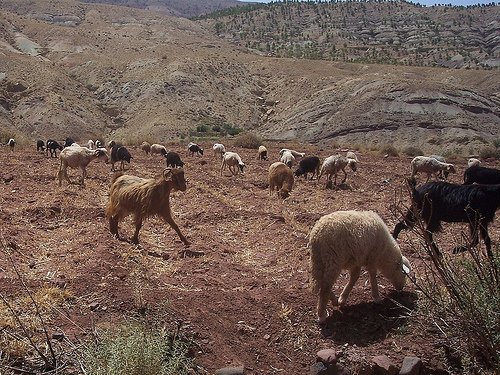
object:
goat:
[164, 148, 185, 170]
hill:
[112, 57, 260, 137]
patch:
[191, 122, 246, 136]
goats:
[267, 161, 292, 199]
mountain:
[213, 2, 498, 72]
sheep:
[3, 129, 494, 316]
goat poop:
[17, 255, 40, 273]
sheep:
[299, 201, 418, 326]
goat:
[94, 157, 190, 249]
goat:
[390, 177, 496, 257]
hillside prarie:
[1, 77, 495, 374]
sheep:
[265, 186, 446, 341]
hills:
[0, 0, 498, 146]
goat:
[108, 142, 138, 170]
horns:
[159, 165, 178, 176]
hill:
[2, 10, 496, 374]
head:
[231, 158, 252, 174]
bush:
[73, 292, 210, 372]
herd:
[3, 132, 490, 313]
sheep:
[106, 146, 196, 249]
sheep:
[267, 162, 295, 197]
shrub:
[83, 307, 188, 372]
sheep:
[409, 155, 458, 183]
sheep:
[465, 157, 480, 167]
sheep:
[317, 155, 357, 187]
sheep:
[346, 148, 360, 162]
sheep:
[276, 148, 306, 158]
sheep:
[257, 143, 268, 160]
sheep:
[221, 152, 246, 172]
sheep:
[212, 142, 225, 159]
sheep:
[54, 144, 111, 186]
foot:
[153, 210, 204, 258]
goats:
[107, 160, 195, 243]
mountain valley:
[1, 5, 493, 373]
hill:
[3, 136, 496, 371]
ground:
[4, 139, 496, 370]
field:
[5, 1, 498, 369]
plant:
[126, 325, 182, 362]